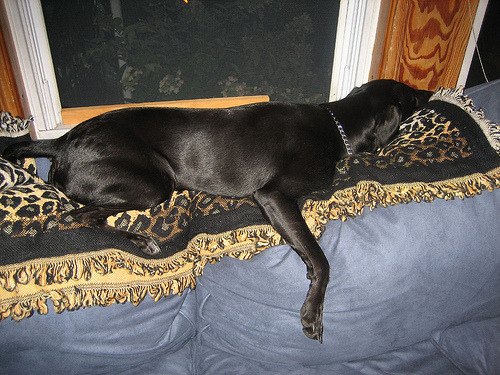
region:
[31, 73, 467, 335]
a black dog laying on a sofa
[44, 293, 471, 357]
blue fabric of the sofa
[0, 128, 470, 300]
a black patterned blanket on the sofa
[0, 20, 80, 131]
white jamb of the window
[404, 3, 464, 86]
brown wooden walls of the room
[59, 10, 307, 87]
green plants growing outside the window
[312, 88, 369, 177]
the dog's chain collar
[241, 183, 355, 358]
the dog's leg hanging over the sofa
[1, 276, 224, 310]
tassles of the blanket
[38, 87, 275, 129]
a pice of wood set on the window sill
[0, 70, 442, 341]
a black dog laying on the couch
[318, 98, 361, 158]
a chain collar on the dog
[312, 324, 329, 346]
dog claws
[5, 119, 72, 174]
tail of the dog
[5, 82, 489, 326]
a cheetah print blanket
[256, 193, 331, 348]
a dog's arm on the side of the couch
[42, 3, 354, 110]
plants outside of the window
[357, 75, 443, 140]
dog has face buried in the couch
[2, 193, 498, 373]
a blue couch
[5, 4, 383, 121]
white trim around the window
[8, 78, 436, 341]
a dog lying down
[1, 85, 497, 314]
the blanket under the dog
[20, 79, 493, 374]
a big blue sofa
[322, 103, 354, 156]
the chain around the dog's neck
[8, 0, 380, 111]
the window next to the dog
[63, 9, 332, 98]
the leaves outside of the window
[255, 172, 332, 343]
the dog's front right leg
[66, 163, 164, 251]
the dog's back right leg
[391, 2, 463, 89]
the wooden wall near to the dog's head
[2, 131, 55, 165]
the top part of the dog's tail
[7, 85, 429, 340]
black dog sleeping on blanket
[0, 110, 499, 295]
cheetah print blanket dog is laying on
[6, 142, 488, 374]
blue couch dog is laying on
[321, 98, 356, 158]
collar of black dog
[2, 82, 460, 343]
black dog laying on back of couch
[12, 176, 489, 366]
back cushions of blue couch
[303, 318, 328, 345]
toe nails of black dog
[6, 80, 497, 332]
fringe of cheetah print blanket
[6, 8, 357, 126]
window behind black dog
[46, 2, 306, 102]
trees outside of window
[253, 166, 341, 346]
front leg of a dog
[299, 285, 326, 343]
paw of a dog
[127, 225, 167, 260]
paw of a dog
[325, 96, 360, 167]
metal collar on a dog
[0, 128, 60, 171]
tail of a dog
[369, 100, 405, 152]
black ear of a dog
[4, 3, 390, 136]
window with a white frame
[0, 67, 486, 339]
dog lying down on a rug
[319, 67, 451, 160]
head of a dog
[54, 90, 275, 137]
peice of wood behind a dog